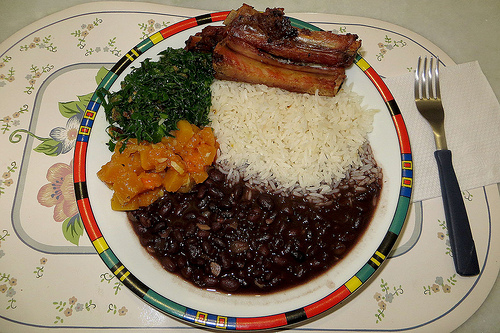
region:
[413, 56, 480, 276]
A fork on a plate.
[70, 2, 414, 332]
Food on a plate.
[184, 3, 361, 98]
Spare ribs on a plate.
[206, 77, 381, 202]
Rice on a plate.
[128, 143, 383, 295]
Beans on a plate.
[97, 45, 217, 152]
Greens on a plate.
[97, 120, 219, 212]
Potatoes on a plate.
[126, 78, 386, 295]
Rice and beans on a plate.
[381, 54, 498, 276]
A fork on a napkin.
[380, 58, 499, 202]
A napkin on the table.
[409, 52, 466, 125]
A clean metallic fork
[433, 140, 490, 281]
Plastic coated metal fork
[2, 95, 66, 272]
Flower designed food tray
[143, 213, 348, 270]
Tasty looking cooked beans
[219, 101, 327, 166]
White colored cooked rice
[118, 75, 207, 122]
Healthy nutritious green vegetables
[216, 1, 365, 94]
Fried tasty looking meat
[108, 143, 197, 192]
Yellow spicy looking dish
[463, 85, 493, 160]
A crisp white serviette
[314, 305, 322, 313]
A red plate patch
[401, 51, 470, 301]
fork with black handle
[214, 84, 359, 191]
a pile of white rice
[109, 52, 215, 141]
greens on a plate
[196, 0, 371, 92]
two ribs on a dinner plate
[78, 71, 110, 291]
dinner plate with colorful edge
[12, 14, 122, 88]
white place mats with colorful design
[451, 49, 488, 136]
napkin under gold fork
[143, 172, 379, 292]
large serving of brown beans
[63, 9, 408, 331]
a large plate of food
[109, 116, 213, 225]
a small serving of carrots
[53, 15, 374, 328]
a plate of food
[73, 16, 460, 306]
food on a plate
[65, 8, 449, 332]
food on a circle plate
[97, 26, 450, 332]
beans on a plate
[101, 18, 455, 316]
rice on a plate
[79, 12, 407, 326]
meat on a plate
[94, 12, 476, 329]
cooked food on a plate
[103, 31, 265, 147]
vegetables on ap late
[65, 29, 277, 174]
cooked greens on a plate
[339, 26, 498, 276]
a fork on a tray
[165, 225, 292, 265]
delicious looking bean stew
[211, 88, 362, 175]
delicious looking rice meal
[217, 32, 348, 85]
two pices of roasted meat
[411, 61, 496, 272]
a blue hadle spoon fork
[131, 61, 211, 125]
green and tasty kales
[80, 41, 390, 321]
A plate of delicious looking meal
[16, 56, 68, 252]
A flower pattern food tray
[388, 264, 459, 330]
A flower pattern food tray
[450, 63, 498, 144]
a white tissue serviette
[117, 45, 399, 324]
A multi colored plate